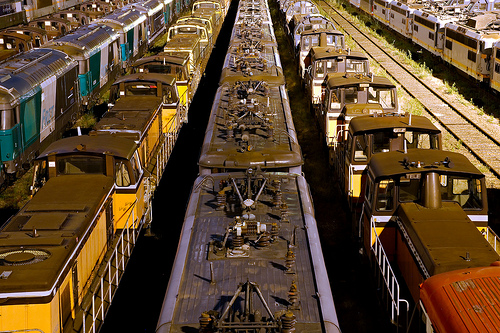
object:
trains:
[150, 1, 343, 331]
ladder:
[368, 217, 401, 317]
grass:
[305, 0, 499, 225]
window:
[395, 169, 485, 212]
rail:
[313, 0, 500, 183]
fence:
[57, 0, 234, 333]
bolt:
[440, 156, 452, 168]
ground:
[316, 0, 500, 190]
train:
[271, 0, 500, 333]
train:
[0, 0, 193, 188]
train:
[0, 0, 236, 333]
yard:
[0, 0, 500, 330]